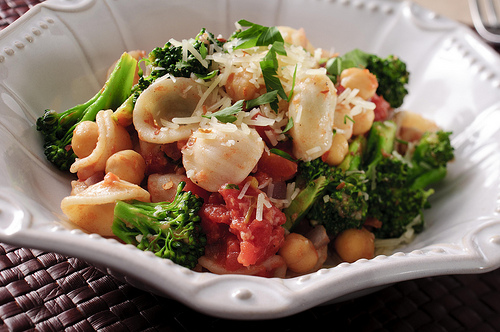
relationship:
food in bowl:
[37, 22, 459, 270] [4, 1, 496, 313]